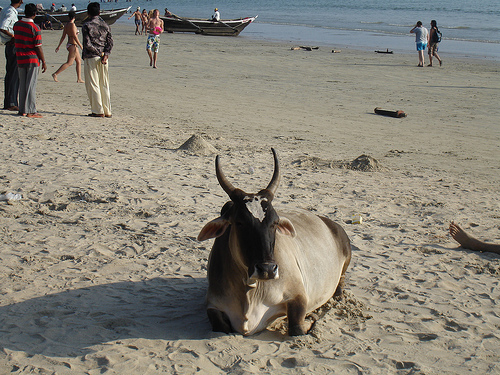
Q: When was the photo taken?
A: Daytime.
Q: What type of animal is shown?
A: Goat.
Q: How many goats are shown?
A: One.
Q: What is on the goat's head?
A: Horns.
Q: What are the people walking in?
A: Sand.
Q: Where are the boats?
A: Water.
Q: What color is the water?
A: Blue.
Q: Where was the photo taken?
A: At the beach.